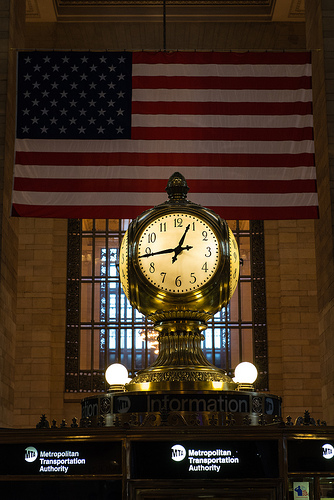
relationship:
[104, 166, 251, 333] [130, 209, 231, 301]
clock has black numbers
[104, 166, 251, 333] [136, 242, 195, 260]
clock has hands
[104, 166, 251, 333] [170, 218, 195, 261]
clock has hour hand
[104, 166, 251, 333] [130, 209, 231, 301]
clock seen face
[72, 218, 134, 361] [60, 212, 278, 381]
bars on a window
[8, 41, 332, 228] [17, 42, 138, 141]
flag has white stars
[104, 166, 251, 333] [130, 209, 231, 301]
clock has face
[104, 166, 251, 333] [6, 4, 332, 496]
clock in station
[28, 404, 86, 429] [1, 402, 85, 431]
chandelier in background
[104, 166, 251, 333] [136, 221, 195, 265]
clock has hands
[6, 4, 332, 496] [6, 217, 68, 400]
building show brick work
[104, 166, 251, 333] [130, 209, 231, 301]
clock with black letters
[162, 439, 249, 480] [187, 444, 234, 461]
sign says metropolitan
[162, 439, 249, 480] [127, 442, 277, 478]
sign has black background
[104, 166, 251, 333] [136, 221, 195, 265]
clock showing 12:44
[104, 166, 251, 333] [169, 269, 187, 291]
clock number 6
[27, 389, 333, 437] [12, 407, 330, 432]
design of metal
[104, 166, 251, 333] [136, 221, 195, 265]
clock face reading 12:45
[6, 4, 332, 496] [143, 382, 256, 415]
station has information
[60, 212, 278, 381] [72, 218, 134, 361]
window has bars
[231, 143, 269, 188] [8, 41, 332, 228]
stripes on us flag